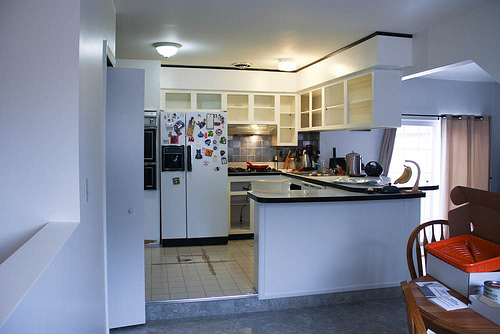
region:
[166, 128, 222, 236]
A fridge in the photo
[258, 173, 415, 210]
A counter in the photo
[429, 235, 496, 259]
A tray in the photo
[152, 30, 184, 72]
A bulb in the photo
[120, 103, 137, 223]
A door in the room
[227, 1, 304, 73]
A ceiling in the room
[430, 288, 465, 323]
A wooden table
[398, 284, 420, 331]
A chair in the photo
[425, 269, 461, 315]
Sheet of paper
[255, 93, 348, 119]
Shelves in the room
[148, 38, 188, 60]
flush mount light on the ceiling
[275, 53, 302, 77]
flush mount light on the ceiling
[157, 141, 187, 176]
black plastic water dispenser on the fridge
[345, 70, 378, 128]
cabinet with a glass door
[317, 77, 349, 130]
cabinet with a glass door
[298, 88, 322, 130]
cabinet with a glass door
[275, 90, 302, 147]
cabinet with a glass door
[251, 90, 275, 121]
cabinet with a glass door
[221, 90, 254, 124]
cabinet with a glass door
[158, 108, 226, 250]
white fridge covered in many magnets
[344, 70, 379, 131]
white cabinet with glass door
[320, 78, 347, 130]
white cabinet with glass door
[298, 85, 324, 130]
white cabinet with glass door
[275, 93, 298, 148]
white cabinet with glass door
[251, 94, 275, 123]
white cabinet with glass door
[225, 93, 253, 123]
white cabinet with glass door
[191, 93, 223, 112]
white cabinet with glass door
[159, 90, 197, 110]
white cabinet with glass door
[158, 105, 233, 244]
white fridge covered in magnets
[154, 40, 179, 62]
light fixture on the ceiling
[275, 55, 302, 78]
light is on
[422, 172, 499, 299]
white box on the table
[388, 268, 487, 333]
chair pushed into the table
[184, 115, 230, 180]
several magnets on the fridge door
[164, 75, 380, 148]
cabinets have no doors on them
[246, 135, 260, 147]
light glare on the tile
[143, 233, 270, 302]
white tile on the kitchen floor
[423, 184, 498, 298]
the box is open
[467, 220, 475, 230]
cutout in the box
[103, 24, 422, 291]
Kitchen with white cupboards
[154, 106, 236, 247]
White two door refrigerator with freezer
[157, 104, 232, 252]
Two door refrigerator with magnets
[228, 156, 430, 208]
Gray kitchen counter in kitchen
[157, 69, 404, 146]
Kitchen cabinets with no doors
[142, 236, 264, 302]
Light tan kitchen tile floor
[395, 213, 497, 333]
Dining room table with two chairs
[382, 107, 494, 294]
Window with beige curtain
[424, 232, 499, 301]
Red painting pan on white box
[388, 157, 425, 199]
Bananas hanging on holder